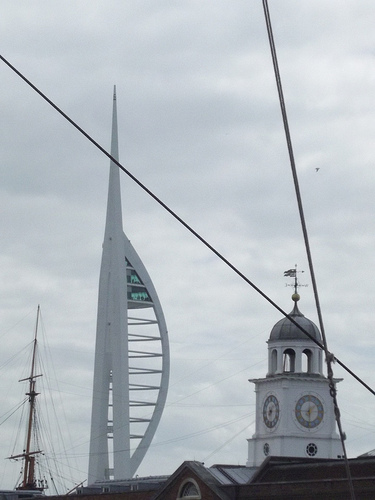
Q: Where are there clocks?
A: White tower.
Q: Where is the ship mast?
A: Left side.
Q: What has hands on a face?
A: Clocks.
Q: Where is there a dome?
A: Top of tower.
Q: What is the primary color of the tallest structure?
A: White.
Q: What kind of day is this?
A: Cloudy.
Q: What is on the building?
A: Large clock.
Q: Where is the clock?
A: On a building.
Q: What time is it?
A: Afternoon.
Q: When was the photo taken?
A: During the daytime.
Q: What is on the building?
A: A clock.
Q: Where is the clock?
A: On the building.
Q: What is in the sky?
A: Clouds.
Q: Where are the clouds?
A: In the sky.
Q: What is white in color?
A: The building and clouds.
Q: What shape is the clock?
A: Circular.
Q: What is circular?
A: Clock.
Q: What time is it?
A: 2:30.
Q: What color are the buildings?
A: White.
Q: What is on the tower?
A: A clock.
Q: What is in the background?
A: A ship.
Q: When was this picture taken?
A: Daytime.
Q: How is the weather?
A: Overcast.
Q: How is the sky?
A: Cloudy.